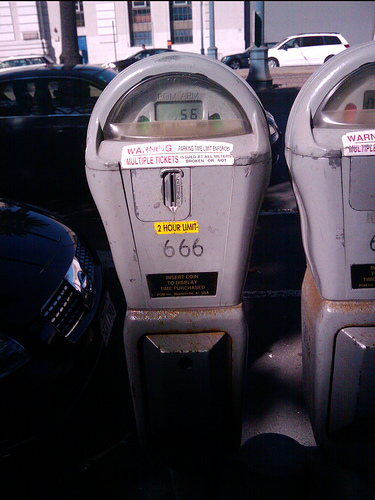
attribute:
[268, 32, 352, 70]
car — white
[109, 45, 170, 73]
car — black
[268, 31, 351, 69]
van — white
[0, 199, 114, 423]
car — dark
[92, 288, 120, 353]
plate — car's, w/ number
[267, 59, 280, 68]
wheel —  car's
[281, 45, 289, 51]
side mirror —  car's, the side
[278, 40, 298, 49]
window —  car's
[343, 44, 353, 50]
indicator —  car's,  red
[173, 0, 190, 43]
window —  building's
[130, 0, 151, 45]
window —  building's,  two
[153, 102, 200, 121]
display —  digital's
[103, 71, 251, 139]
cover —  clear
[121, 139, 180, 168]
words —  red,  label's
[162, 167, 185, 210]
slot —  coin's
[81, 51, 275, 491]
meter — for parking,  gray,  two,  mettalic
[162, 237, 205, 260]
numbers —  three ,  black, in gray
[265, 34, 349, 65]
car —  white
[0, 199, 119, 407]
car — black,  blue,  the front,  parked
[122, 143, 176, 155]
sticker —  white,  warning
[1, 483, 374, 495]
bottom —  black,  of photo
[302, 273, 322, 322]
rust —  meter's